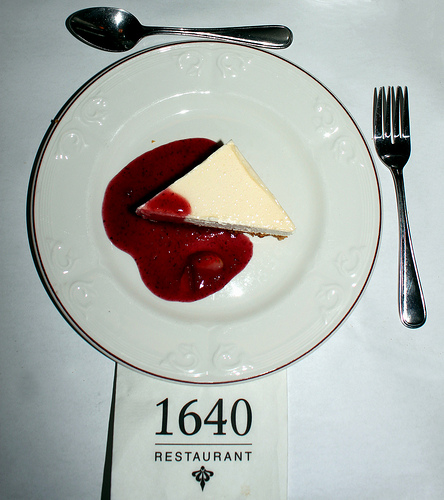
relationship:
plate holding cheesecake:
[22, 36, 386, 388] [134, 140, 293, 237]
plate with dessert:
[296, 128, 342, 188] [135, 140, 298, 240]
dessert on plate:
[141, 140, 296, 261] [22, 46, 392, 389]